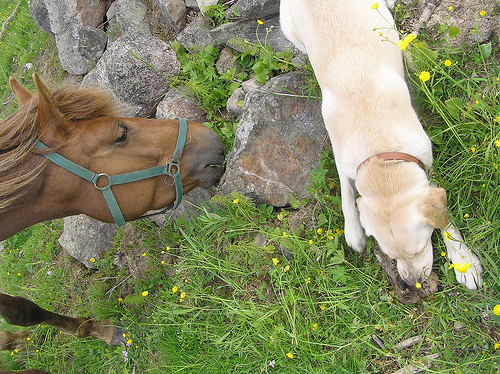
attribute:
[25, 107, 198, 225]
harness — green, blue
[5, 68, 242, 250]
horse — looking, coffee colored, eating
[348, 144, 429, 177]
collar — brown, leather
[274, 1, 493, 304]
dog — sniffing, digging, tan, white, yellow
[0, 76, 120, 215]
mane — brown, bushy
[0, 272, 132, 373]
legs — fat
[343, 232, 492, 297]
paws — white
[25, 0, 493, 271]
rocks — lined, large, piled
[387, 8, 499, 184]
flowers — yellow, blooming, small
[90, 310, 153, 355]
hooves — brown, black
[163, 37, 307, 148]
grass — green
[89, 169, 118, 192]
circle — round, metal